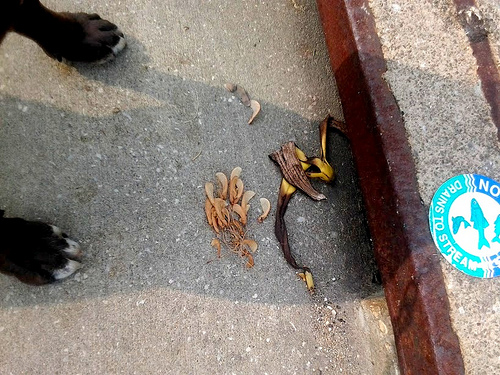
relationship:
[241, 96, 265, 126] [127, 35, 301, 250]
seed on ground